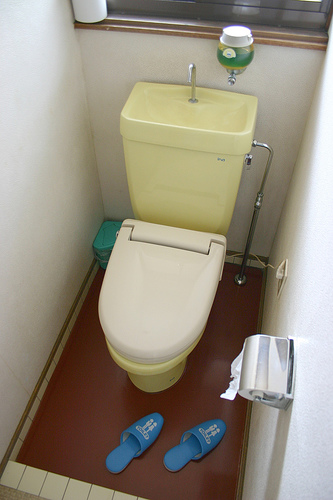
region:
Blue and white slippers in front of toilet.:
[102, 403, 228, 486]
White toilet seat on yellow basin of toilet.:
[94, 216, 233, 368]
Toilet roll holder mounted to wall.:
[219, 328, 305, 416]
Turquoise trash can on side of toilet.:
[88, 216, 126, 265]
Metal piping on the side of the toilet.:
[231, 138, 263, 293]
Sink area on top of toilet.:
[128, 58, 261, 155]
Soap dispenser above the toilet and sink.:
[219, 18, 257, 89]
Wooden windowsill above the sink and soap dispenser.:
[76, 12, 328, 49]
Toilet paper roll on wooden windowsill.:
[74, 0, 106, 24]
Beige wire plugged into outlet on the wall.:
[227, 245, 288, 281]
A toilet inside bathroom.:
[87, 209, 230, 396]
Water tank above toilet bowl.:
[120, 136, 251, 234]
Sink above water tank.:
[130, 58, 259, 145]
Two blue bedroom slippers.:
[97, 407, 231, 486]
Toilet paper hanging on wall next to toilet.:
[219, 328, 289, 416]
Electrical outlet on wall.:
[266, 257, 301, 300]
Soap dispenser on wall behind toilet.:
[217, 26, 264, 91]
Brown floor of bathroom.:
[36, 378, 98, 476]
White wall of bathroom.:
[13, 225, 50, 344]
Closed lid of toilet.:
[105, 219, 231, 365]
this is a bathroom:
[10, 47, 309, 478]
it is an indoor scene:
[15, 66, 298, 494]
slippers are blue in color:
[82, 383, 234, 498]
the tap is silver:
[181, 56, 199, 108]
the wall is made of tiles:
[4, 370, 40, 430]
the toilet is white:
[80, 221, 231, 402]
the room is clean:
[9, 59, 309, 489]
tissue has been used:
[206, 319, 314, 466]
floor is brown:
[53, 431, 116, 479]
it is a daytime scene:
[18, 1, 331, 157]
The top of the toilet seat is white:
[109, 213, 234, 388]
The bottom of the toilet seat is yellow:
[104, 348, 208, 399]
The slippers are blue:
[103, 420, 242, 485]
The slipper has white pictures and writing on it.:
[134, 415, 169, 442]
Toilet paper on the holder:
[237, 329, 302, 428]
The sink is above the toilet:
[99, 62, 296, 157]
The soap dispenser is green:
[216, 24, 268, 92]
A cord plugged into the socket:
[268, 250, 308, 304]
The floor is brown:
[37, 379, 241, 449]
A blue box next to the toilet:
[95, 216, 124, 265]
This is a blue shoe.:
[99, 396, 166, 488]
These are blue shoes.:
[95, 398, 224, 495]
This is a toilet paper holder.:
[221, 338, 308, 426]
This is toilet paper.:
[223, 330, 256, 418]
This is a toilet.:
[94, 315, 195, 410]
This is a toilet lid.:
[79, 213, 245, 374]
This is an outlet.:
[252, 246, 310, 310]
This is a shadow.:
[248, 394, 297, 498]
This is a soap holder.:
[207, 14, 264, 85]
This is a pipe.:
[220, 137, 285, 297]